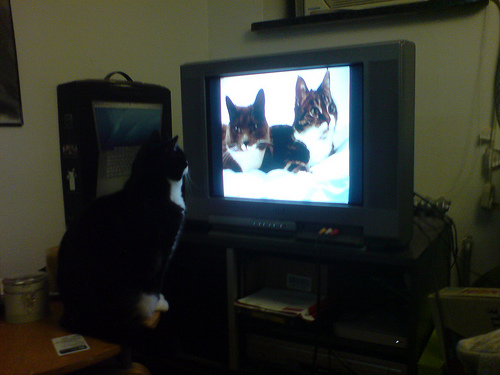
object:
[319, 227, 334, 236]
cables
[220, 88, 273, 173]
cats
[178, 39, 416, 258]
tv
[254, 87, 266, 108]
ear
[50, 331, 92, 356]
paper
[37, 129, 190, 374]
cat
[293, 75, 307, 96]
ear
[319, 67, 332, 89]
ear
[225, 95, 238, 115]
ear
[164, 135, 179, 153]
ear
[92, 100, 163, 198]
laptop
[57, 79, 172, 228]
box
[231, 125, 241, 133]
eye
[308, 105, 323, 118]
eye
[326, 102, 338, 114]
eye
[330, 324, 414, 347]
dvd player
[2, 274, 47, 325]
container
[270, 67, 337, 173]
cat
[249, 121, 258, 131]
eye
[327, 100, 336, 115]
eye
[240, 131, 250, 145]
nose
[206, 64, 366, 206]
screen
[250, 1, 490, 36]
shelf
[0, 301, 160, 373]
table